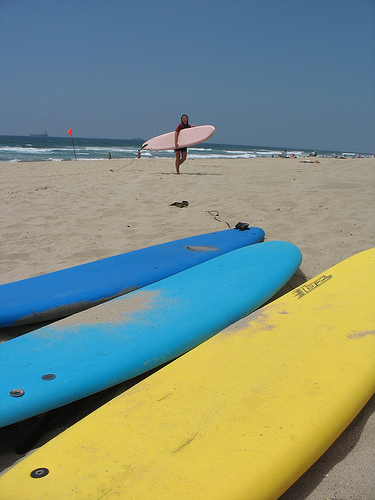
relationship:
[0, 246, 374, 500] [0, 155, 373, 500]
laying on beach.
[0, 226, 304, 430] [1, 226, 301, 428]
two blue surfboards.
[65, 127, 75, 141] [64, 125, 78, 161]
orange on stick.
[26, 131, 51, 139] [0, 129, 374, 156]
boat on horizon.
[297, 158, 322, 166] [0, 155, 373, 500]
laying on beach.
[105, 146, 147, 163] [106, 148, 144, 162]
two people walking.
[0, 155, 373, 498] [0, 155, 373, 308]
sand brown sand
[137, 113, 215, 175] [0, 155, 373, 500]
surfer on beach.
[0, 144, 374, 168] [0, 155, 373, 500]
waves on beach.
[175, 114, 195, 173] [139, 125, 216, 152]
surfer carrying surfboard.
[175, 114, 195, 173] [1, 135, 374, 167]
surfer away from.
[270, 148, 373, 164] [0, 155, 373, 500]
sitting on beach.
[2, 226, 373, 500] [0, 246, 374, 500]
three surfboards laying.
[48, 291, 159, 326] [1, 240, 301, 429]
sand on surfboard.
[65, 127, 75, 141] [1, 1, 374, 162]
flag in wind.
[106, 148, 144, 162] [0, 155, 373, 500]
walking on beach.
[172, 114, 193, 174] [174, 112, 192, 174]
black and red.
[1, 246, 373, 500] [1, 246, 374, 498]
plain yellow surfboard.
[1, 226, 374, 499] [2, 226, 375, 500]
row of surfboards.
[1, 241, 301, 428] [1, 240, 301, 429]
bright blue surfboard.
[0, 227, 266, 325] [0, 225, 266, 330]
dark blue surfboard.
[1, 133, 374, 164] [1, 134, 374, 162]
turbluent sea water.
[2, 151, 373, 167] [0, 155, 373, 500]
edge of beach.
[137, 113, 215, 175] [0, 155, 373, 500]
surfboarder on beach.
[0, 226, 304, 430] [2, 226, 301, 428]
blue surfboards laying.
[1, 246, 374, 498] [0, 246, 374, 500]
yellow surfboard laying.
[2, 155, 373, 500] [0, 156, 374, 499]
beige dry sand.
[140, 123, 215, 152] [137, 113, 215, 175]
surfboard being carried.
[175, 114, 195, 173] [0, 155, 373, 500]
surfer on beach.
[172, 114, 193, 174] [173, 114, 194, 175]
black red swimsuit.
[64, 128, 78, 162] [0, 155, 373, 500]
flag on beach.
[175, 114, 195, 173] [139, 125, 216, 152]
surfer holding surfboard.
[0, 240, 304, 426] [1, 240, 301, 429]
light blue surfboard.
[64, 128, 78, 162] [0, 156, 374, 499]
flag in sand.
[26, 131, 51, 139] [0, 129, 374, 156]
boat in distance.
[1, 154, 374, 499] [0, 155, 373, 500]
brown sandy beach.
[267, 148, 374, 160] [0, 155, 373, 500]
sitting on beach.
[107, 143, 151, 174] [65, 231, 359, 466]
black leash for surfboard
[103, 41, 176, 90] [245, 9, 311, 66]
sky with no clouds